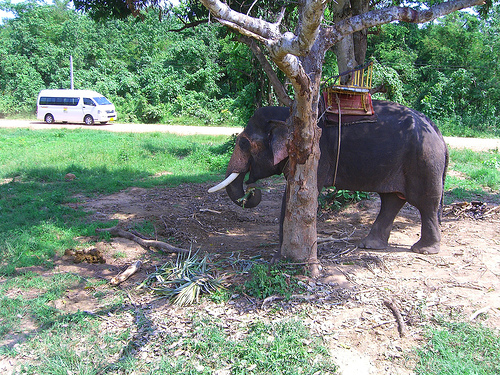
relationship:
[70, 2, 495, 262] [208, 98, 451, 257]
tree in front of elephant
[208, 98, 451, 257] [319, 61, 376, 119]
elephant has saddle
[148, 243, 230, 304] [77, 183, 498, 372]
branches on ground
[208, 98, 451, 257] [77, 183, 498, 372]
elephant on ground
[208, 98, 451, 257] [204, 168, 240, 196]
elephant has tusk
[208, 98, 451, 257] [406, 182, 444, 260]
elephant has leg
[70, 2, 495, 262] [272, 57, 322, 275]
tree has trunk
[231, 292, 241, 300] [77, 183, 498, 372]
rock on ground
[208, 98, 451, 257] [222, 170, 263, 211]
elephant has trunk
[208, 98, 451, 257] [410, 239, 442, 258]
elephant has foot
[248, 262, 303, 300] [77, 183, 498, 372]
leaves on ground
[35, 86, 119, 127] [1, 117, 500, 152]
van on road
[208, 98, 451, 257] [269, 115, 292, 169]
elephant has ear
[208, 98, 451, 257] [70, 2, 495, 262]
elephant behind tree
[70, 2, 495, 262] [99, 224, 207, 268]
tree has root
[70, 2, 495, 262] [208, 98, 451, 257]
tree in front elephant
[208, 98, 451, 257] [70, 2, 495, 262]
elephant amongst tree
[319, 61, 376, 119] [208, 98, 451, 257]
seat on elephant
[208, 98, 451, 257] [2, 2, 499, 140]
elephant in trees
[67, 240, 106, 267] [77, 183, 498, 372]
feces on ground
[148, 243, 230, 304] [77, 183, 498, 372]
trees on ground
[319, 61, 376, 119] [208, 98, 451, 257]
chair on elephant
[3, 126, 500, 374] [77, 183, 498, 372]
grass on ground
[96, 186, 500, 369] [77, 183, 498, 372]
dirt on ground